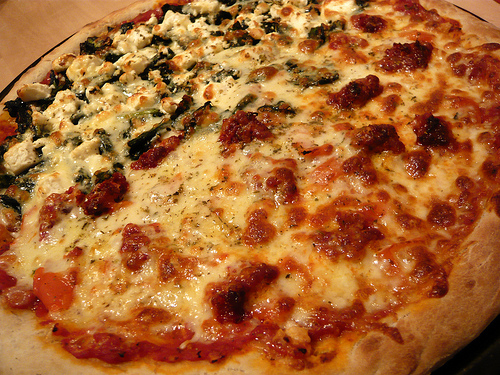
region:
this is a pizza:
[1, 3, 496, 368]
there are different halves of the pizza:
[2, 6, 477, 373]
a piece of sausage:
[319, 64, 389, 102]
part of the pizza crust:
[362, 315, 483, 373]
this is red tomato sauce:
[73, 334, 175, 364]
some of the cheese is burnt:
[188, 240, 288, 328]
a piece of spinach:
[102, 89, 239, 161]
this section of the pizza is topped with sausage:
[303, 66, 486, 238]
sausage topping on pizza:
[309, 38, 454, 180]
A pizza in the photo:
[182, 104, 355, 289]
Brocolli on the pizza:
[133, 119, 154, 159]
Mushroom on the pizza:
[14, 130, 43, 171]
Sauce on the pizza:
[285, 219, 360, 303]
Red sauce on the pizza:
[212, 277, 272, 325]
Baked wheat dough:
[421, 300, 466, 350]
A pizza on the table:
[141, 67, 476, 330]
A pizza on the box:
[155, 112, 376, 275]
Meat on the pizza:
[217, 108, 267, 153]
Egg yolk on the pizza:
[309, 267, 346, 305]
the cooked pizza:
[0, 0, 498, 373]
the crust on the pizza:
[0, 0, 499, 373]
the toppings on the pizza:
[0, 0, 499, 372]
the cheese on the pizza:
[0, 0, 498, 373]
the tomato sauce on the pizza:
[0, 0, 498, 373]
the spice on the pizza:
[285, 273, 290, 278]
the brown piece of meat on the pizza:
[217, 109, 276, 159]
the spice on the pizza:
[75, 170, 127, 217]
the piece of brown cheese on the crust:
[367, 321, 403, 343]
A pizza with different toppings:
[2, 1, 499, 369]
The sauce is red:
[187, 339, 234, 361]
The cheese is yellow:
[90, 291, 123, 315]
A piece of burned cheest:
[213, 259, 275, 319]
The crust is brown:
[352, 211, 498, 374]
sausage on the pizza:
[220, 110, 266, 145]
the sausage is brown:
[353, 123, 403, 154]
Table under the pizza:
[0, 1, 498, 93]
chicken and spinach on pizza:
[3, 0, 368, 215]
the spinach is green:
[95, 126, 115, 152]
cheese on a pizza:
[303, 264, 346, 311]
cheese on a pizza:
[105, 283, 169, 330]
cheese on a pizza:
[406, 156, 454, 210]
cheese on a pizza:
[353, 120, 388, 155]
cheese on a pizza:
[152, 133, 213, 188]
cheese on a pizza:
[438, 54, 480, 98]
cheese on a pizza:
[338, 26, 373, 69]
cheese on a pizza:
[185, 144, 220, 188]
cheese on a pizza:
[132, 173, 172, 228]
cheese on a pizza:
[62, 228, 122, 270]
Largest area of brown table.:
[1, 1, 140, 90]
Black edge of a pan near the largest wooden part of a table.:
[0, 31, 83, 101]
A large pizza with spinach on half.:
[1, 0, 497, 373]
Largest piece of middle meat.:
[219, 113, 270, 148]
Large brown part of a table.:
[1, 1, 141, 91]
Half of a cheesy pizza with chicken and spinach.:
[2, 0, 353, 251]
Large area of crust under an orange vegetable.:
[1, 306, 111, 373]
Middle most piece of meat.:
[223, 111, 271, 148]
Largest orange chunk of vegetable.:
[29, 266, 76, 316]